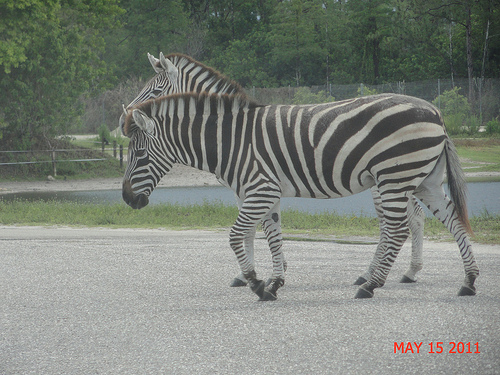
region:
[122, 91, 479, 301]
a black and white zebra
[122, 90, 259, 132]
the brown mane on the back of the neck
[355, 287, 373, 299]
the zebras hooves are black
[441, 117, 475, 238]
the zebras tail has long hair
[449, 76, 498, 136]
a fence runs along the boarder of the zebra pen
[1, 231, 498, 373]
a paved road in the zebra display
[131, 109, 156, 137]
a zebras white ears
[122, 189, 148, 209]
the zebra has a black nose and lips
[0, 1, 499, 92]
tall trees run along the fence line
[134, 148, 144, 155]
zebra eyes are black and blend in with the stripes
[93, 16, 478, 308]
There are 2 zebras.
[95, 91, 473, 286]
The zebras are black and white.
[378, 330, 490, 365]
The date is May 15 2011.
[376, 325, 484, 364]
The text is red.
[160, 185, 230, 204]
The water is blue.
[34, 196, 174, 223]
The grass is green.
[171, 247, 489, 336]
The zebras are walking on concrete.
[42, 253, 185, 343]
The concrete is grey.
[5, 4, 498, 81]
Trees are in the background.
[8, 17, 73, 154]
The leaves are green.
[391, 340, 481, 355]
Photo's red date stamp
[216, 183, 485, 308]
Legs of two zebras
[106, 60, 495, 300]
Two walking zebras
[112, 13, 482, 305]
Two zebras walking on the pavement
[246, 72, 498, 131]
Fence to keep zebras in captivity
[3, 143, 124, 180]
Fence to keep zebras out of woods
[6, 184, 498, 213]
Water for the zebras to drink and bathe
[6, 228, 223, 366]
grey pavement for zebras to walk on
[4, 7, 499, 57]
green trees in background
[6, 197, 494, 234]
Grass between pavement and water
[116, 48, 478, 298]
two zebras cross the street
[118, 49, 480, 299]
a pair of zebras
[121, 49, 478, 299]
a zebra duo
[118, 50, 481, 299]
a pair of zebras walking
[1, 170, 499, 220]
a pool of water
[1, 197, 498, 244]
grass along the water's edge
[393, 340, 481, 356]
the date is may 15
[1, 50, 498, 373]
zebras walk on a street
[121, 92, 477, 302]
one zebra is in front of the other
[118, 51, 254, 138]
one zebra is behind the other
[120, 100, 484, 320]
zebra in the picture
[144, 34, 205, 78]
the ears of the second zebra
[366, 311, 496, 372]
the date the photo was taken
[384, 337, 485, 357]
May 15 2011 was the date this photo was taken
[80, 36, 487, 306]
two zebras walking together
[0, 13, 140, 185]
the trees in the back ground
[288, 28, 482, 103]
the fence in the back ground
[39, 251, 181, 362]
the cement on the ground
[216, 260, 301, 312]
the hoods of the zebras walking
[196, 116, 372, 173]
the stripes of the zebra